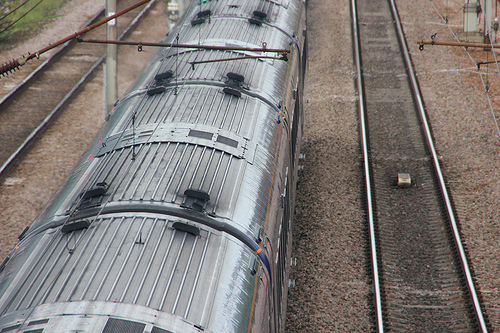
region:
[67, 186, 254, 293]
Train is grey color.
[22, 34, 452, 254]
Three tracks are seen.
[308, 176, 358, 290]
Gravel is brown color.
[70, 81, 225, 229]
Train is on track.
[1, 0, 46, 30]
Grass is green color.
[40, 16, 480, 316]
Day time picture.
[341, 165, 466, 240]
Track is grey color.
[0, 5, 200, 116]
Power cord is running above the train.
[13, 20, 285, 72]
Rod is brown color.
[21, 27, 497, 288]
Tracks are running parallel to each other.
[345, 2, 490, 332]
empty train track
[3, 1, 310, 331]
roof of a train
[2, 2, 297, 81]
rusty bars above the train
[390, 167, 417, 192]
small metal square on the train track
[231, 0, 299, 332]
thin yellow stripe on the side of the train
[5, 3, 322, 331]
metal roofs of train cars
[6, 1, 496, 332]
a train between two empty tracks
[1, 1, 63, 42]
small patch of grass in the background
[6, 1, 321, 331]
a silver passenger train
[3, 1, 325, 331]
a passenger train with a shiny silver roof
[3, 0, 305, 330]
the train is silver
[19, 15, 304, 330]
two of the train cars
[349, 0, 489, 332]
an empty train track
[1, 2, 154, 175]
a track with no train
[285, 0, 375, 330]
the ground is gravel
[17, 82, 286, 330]
one of the train cars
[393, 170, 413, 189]
a box on the train track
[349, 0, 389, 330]
one of the rails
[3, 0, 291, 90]
rusty poles above train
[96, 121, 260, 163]
vents on top of the train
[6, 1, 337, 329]
top of silver train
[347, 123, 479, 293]
track next to train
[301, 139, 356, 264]
brown rocks next to train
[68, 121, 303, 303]
silver train on tracks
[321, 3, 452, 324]
long tracks on ground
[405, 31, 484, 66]
long brown thing next to track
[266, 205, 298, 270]
windows on train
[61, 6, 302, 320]
four cars of the train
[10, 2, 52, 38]
grass next to train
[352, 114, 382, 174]
silver side of track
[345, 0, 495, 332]
a pair of train tracks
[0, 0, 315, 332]
a long gray train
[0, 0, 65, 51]
a patch of green grass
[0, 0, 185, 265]
gravel by the train tracks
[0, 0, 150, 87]
a rust colored bar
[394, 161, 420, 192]
a metal post in the ground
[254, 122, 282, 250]
a yellow stripe on the train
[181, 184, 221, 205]
a black piece of metal on the train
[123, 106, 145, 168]
a wire on the train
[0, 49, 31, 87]
a spiky metal bar